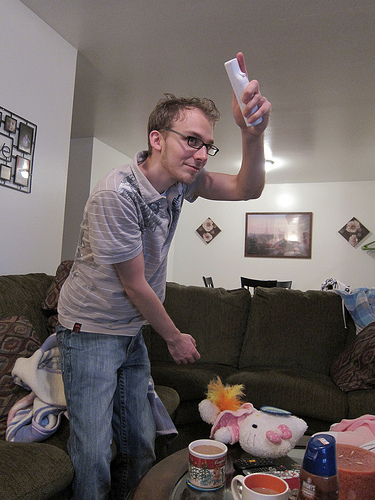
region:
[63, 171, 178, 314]
the shirt is grey and white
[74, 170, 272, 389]
the collared shirt is striped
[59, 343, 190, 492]
the jeans are baggy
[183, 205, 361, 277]
the wall is decorated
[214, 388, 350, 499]
the table is very cluttered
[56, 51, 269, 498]
the man is standing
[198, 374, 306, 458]
the hello kitty on the coffee table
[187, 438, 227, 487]
the coffee mug on the table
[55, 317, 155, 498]
the blue jeans on the man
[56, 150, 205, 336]
the shirt on the man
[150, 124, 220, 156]
the glasses on the man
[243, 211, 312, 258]
the picture on the wall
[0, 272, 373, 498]
the couch behind the man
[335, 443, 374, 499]
the large candle on the table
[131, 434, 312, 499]
the coffee table in front of the man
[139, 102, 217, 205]
man is wearing eyeglasses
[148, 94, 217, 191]
man is wearing eyeglasses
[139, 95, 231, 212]
man is wearing eyeglasses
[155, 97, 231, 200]
man is wearing eyeglasses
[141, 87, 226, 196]
man is wearing eyeglasses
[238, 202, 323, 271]
painting on the wall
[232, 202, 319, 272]
painting on the wall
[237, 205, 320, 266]
painting on the wall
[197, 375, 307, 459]
the pink and white hello kitty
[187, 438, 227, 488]
the coffee mug on the coffee table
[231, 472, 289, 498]
the orange and white coffee mug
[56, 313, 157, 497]
the blue jeans on the man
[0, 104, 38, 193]
the pictures on the wall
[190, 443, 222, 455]
the liquid in the coffee mug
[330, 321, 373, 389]
the pillow on the sectional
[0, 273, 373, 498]
the sectional behind the man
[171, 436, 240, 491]
red white and green cup of tea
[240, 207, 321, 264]
large picture on the wall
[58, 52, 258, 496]
young man playing a video game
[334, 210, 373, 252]
flower picture on the wall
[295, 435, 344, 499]
blue top of a creamer bottle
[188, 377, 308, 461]
stuffed Hello Kitty plush on the table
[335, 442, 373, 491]
top of a large red candle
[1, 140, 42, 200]
corner of a metal picture holder on the wall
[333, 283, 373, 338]
blue plaid jacket on the couch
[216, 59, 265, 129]
white video game controller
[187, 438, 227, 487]
the coffee cup on the table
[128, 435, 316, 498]
the coffee table in front of the man